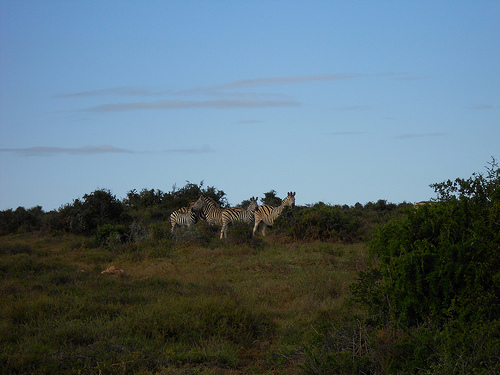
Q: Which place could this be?
A: It is a field.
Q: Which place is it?
A: It is a field.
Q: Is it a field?
A: Yes, it is a field.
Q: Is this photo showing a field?
A: Yes, it is showing a field.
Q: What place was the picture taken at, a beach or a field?
A: It was taken at a field.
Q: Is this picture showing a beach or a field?
A: It is showing a field.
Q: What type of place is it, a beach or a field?
A: It is a field.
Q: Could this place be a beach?
A: No, it is a field.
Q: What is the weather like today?
A: It is clear.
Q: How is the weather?
A: It is clear.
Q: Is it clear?
A: Yes, it is clear.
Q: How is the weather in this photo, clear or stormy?
A: It is clear.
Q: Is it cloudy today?
A: No, it is clear.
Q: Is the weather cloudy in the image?
A: No, it is clear.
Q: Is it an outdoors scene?
A: Yes, it is outdoors.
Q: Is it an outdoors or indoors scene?
A: It is outdoors.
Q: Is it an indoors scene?
A: No, it is outdoors.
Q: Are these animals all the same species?
A: Yes, all the animals are zebras.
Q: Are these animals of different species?
A: No, all the animals are zebras.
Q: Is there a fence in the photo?
A: No, there are no fences.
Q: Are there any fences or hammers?
A: No, there are no fences or hammers.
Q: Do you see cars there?
A: No, there are no cars.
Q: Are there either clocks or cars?
A: No, there are no cars or clocks.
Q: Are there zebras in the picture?
A: Yes, there is a zebra.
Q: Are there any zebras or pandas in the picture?
A: Yes, there is a zebra.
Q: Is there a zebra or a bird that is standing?
A: Yes, the zebra is standing.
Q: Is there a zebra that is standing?
A: Yes, there is a zebra that is standing.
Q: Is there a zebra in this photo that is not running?
A: Yes, there is a zebra that is standing.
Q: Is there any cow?
A: No, there are no cows.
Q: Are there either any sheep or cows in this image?
A: No, there are no cows or sheep.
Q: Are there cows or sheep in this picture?
A: No, there are no cows or sheep.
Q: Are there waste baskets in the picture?
A: No, there are no waste baskets.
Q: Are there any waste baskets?
A: No, there are no waste baskets.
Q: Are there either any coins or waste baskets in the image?
A: No, there are no waste baskets or coins.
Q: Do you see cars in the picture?
A: No, there are no cars.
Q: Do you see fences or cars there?
A: No, there are no cars or fences.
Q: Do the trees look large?
A: Yes, the trees are large.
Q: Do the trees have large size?
A: Yes, the trees are large.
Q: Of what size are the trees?
A: The trees are large.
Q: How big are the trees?
A: The trees are large.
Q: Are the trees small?
A: No, the trees are large.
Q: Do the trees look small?
A: No, the trees are large.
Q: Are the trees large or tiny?
A: The trees are large.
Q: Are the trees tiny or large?
A: The trees are large.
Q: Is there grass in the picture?
A: Yes, there is grass.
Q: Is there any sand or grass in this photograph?
A: Yes, there is grass.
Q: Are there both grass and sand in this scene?
A: No, there is grass but no sand.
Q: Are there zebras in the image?
A: Yes, there are zebras.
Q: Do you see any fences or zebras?
A: Yes, there are zebras.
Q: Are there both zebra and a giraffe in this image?
A: No, there are zebras but no giraffes.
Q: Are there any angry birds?
A: No, there are no angry birds.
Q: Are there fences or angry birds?
A: No, there are no angry birds or fences.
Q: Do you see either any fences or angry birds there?
A: No, there are no angry birds or fences.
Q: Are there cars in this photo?
A: No, there are no cars.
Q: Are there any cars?
A: No, there are no cars.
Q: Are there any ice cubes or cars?
A: No, there are no cars or ice cubes.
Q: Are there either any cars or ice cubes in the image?
A: No, there are no cars or ice cubes.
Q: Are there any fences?
A: No, there are no fences.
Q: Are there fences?
A: No, there are no fences.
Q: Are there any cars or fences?
A: No, there are no fences or cars.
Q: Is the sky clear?
A: Yes, the sky is clear.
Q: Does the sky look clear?
A: Yes, the sky is clear.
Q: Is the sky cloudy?
A: No, the sky is clear.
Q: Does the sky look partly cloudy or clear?
A: The sky is clear.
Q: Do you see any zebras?
A: Yes, there is a zebra.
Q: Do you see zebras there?
A: Yes, there is a zebra.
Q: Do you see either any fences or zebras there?
A: Yes, there is a zebra.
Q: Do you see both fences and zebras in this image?
A: No, there is a zebra but no fences.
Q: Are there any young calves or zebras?
A: Yes, there is a young zebra.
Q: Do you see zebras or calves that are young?
A: Yes, the zebra is young.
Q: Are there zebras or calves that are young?
A: Yes, the zebra is young.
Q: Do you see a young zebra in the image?
A: Yes, there is a young zebra.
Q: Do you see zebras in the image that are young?
A: Yes, there is a young zebra.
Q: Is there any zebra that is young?
A: Yes, there is a zebra that is young.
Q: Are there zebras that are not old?
A: Yes, there is an young zebra.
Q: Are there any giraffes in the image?
A: No, there are no giraffes.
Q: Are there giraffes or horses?
A: No, there are no giraffes or horses.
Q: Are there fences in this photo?
A: No, there are no fences.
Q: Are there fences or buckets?
A: No, there are no fences or buckets.